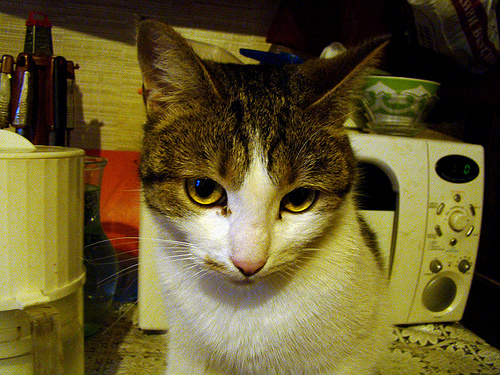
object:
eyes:
[182, 171, 324, 215]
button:
[411, 244, 496, 306]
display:
[428, 142, 495, 189]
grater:
[14, 21, 84, 88]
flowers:
[382, 319, 460, 372]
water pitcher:
[0, 124, 92, 374]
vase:
[72, 154, 119, 362]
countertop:
[33, 296, 499, 373]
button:
[421, 273, 458, 314]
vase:
[80, 159, 130, 347]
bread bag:
[423, 2, 468, 74]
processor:
[0, 132, 89, 373]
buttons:
[426, 195, 473, 281]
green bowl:
[352, 74, 441, 134]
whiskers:
[76, 214, 353, 318]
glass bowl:
[355, 73, 441, 136]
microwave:
[139, 115, 486, 332]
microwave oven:
[135, 124, 483, 334]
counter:
[382, 327, 495, 373]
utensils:
[3, 31, 90, 174]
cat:
[134, 18, 393, 373]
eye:
[280, 184, 319, 213]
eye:
[182, 177, 226, 207]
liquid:
[80, 156, 119, 337]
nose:
[230, 252, 267, 279]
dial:
[447, 209, 473, 232]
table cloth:
[416, 310, 444, 351]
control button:
[409, 143, 483, 323]